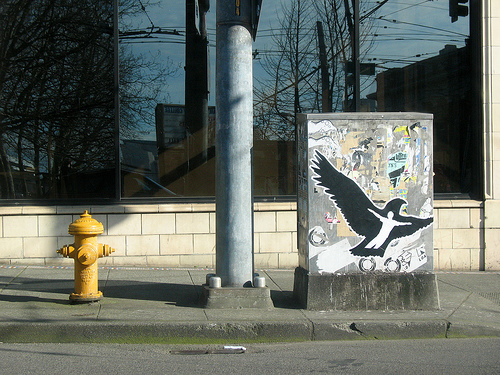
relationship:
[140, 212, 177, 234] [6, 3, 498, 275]
tile on building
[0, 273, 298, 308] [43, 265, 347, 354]
shadow on sidewalk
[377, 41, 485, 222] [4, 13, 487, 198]
building with window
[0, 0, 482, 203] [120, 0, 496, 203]
reflection in window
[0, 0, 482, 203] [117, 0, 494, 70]
reflection of power lines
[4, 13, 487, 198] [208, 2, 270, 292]
window behind pole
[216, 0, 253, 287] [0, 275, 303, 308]
pole casts shadow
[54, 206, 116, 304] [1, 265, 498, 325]
fire hydrant on sidewalk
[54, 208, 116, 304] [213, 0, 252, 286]
fire hydrant near pole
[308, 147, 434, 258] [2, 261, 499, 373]
bird art on concrete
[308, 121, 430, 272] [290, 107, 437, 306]
graffiti on pillar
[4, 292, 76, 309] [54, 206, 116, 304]
shadow of fire hydrant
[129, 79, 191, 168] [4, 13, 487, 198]
reflection in a window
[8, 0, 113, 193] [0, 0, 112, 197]
tree reflection on window